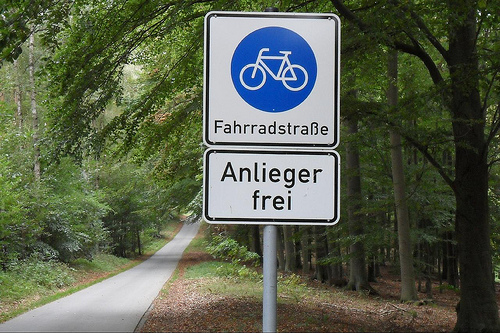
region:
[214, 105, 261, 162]
part of a board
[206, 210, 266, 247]
edge of a board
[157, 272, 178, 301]
edge of a road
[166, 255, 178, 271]
edge of a road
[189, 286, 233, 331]
this is the ground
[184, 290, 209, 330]
the ground is full of dry leaves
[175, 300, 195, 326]
the leaves are brown in color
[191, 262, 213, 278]
this is the grass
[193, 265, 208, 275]
the grass is green in color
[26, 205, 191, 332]
this is a path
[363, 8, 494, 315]
these are several leaves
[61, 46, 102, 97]
the leaves are green in color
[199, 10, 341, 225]
this is a signboard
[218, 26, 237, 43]
the signboard is white in color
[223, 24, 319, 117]
a white bicycle in a blue circle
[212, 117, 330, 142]
beneath it 'fahrradstrae', capital 'f', meaning [in american]: bike path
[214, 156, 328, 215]
'anlieger frei', capital 'a', meaning [in american]: residents only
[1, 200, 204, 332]
to the left, a very pretty, very clean bike path for no-one but residents, apparently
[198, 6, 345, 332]
both signs on white, outlined in black, stuck to round metal pole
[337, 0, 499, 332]
a very pretty fairytale type dark tree far right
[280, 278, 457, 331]
some dry bark amid dry leaves near the trees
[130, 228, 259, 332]
dry leaves amid grass near bike path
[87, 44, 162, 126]
fanciful looking sunlight comes through the leaves top mid-left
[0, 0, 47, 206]
thin white, knobby barked trees, maybe birch, @ mid-left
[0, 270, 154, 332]
a bike path in the woods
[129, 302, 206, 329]
leaves by the sidewalk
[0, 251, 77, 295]
plants on the hill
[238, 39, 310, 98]
a white bicycle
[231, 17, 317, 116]
a blue circle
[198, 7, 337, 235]
a white sign on the path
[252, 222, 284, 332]
a pole for the sign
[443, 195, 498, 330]
the trunk of a tree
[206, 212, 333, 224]
the black outline on sign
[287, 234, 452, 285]
a row of trees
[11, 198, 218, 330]
a paved bike path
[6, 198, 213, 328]
a paved walking path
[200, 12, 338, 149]
a blue and white bicycle sign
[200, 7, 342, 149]
a sign in German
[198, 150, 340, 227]
a white sign in German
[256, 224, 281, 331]
a tall metal pole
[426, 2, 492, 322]
a tall tree trunk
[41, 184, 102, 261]
a large green bush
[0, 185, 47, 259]
a large green bush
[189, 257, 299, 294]
a patch of green grass